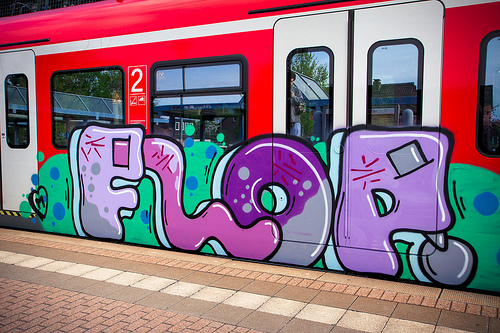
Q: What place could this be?
A: It is a sidewalk.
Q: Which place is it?
A: It is a sidewalk.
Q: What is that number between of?
A: The number is between the doors.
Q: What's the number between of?
A: The number is between the doors.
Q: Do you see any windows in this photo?
A: Yes, there is a window.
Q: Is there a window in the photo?
A: Yes, there is a window.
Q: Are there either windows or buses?
A: Yes, there is a window.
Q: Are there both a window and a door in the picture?
A: Yes, there are both a window and a door.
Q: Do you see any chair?
A: No, there are no chairs.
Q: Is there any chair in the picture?
A: No, there are no chairs.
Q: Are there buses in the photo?
A: No, there are no buses.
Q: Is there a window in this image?
A: Yes, there is a window.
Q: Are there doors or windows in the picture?
A: Yes, there is a window.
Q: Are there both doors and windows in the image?
A: Yes, there are both a window and a door.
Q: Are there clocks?
A: No, there are no clocks.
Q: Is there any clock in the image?
A: No, there are no clocks.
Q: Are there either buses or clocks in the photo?
A: No, there are no clocks or buses.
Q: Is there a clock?
A: No, there are no clocks.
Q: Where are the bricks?
A: The bricks are on the sidewalk.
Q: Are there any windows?
A: Yes, there is a window.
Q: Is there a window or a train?
A: Yes, there is a window.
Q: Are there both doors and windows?
A: Yes, there are both a window and a door.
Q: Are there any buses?
A: No, there are no buses.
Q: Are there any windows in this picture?
A: Yes, there is a window.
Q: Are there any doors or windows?
A: Yes, there is a window.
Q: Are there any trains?
A: Yes, there is a train.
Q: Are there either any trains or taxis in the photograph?
A: Yes, there is a train.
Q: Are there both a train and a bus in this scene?
A: No, there is a train but no buses.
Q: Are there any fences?
A: No, there are no fences.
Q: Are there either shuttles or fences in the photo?
A: No, there are no fences or shuttles.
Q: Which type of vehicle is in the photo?
A: The vehicle is a train.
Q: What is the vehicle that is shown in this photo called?
A: The vehicle is a train.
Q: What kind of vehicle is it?
A: The vehicle is a train.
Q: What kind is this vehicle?
A: This is a train.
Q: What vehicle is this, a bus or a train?
A: This is a train.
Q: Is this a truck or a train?
A: This is a train.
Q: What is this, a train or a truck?
A: This is a train.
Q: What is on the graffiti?
A: The train is on the graffiti.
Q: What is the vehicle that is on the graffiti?
A: The vehicle is a train.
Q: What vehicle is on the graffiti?
A: The vehicle is a train.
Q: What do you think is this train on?
A: The train is on the graffiti.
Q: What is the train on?
A: The train is on the graffiti.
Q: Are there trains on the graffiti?
A: Yes, there is a train on the graffiti.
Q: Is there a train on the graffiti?
A: Yes, there is a train on the graffiti.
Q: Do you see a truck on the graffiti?
A: No, there is a train on the graffiti.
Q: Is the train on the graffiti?
A: Yes, the train is on the graffiti.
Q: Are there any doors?
A: Yes, there is a door.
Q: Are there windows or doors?
A: Yes, there is a door.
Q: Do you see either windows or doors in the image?
A: Yes, there is a door.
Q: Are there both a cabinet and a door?
A: No, there is a door but no cabinets.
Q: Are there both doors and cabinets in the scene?
A: No, there is a door but no cabinets.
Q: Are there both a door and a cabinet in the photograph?
A: No, there is a door but no cabinets.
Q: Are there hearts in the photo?
A: Yes, there is a heart.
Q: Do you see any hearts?
A: Yes, there is a heart.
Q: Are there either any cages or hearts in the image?
A: Yes, there is a heart.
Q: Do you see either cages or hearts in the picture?
A: Yes, there is a heart.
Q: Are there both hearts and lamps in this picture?
A: No, there is a heart but no lamps.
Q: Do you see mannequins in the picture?
A: No, there are no mannequins.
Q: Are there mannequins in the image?
A: No, there are no mannequins.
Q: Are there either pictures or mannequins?
A: No, there are no mannequins or pictures.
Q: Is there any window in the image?
A: Yes, there is a window.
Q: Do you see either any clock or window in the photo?
A: Yes, there is a window.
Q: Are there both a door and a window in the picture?
A: Yes, there are both a window and a door.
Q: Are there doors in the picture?
A: Yes, there are doors.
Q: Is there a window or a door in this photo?
A: Yes, there are doors.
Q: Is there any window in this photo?
A: Yes, there is a window.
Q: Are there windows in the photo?
A: Yes, there is a window.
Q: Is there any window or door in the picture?
A: Yes, there is a window.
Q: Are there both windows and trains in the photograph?
A: Yes, there are both a window and a train.